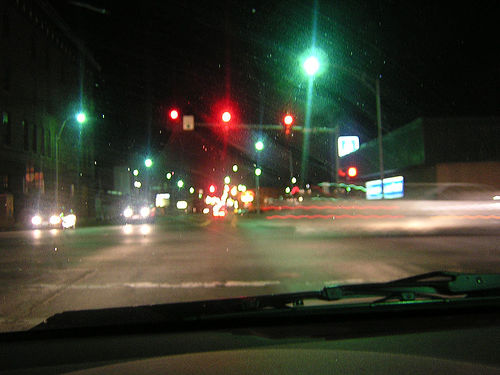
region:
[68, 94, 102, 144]
A green light on a pole.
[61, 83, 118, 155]
A green bright light on a pole.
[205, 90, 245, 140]
A red bright light on a pole.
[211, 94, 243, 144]
A red bright traffic light on a pole.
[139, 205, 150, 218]
A white bright light on a car.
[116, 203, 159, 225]
White bright lights on a car.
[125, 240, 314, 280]
The street in the city.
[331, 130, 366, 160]
A sign in the city.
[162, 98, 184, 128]
A red traffic light.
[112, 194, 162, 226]
A car on the street.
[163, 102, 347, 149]
Traffic lights showing red light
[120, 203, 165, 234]
Head lights on a car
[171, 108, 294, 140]
Red traffic light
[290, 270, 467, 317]
windshield wiper on a car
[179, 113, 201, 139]
traffic sign on a pole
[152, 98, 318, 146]
Red light of traffic pole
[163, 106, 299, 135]
Red light of traffic pole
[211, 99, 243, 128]
Bright red light in pole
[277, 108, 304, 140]
Bright red light in pole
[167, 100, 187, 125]
Bright red light in pole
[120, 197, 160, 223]
Headlights on a car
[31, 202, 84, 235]
Headlights on a car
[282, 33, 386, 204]
Bright light on a pole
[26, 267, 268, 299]
White line on pavement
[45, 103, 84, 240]
Bright light on a pole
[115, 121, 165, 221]
Bright light on a pole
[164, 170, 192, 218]
Bright light on a pole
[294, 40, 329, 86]
a green traffic light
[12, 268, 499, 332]
windshield wipers on the front of the car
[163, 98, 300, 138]
a set of three red traffic lights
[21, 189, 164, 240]
oncoming traffic with their headlights on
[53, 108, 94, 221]
a street light on the side of the road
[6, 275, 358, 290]
a white line painted on the street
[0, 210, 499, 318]
a city street at night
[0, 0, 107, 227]
a building on the side of the street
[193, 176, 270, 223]
a bunch of bright lights in the distance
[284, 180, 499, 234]
a car moving through the intersection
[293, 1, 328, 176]
a green light in the dark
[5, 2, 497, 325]
a city street at night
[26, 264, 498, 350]
a windshield wiper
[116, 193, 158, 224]
a car facing forward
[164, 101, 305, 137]
the traffic light is on red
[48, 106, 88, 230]
another green streetlight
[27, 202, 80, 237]
a car under the streetlight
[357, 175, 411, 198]
a blue sign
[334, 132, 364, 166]
a green streetlight on the right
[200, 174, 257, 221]
lights clumped in a group